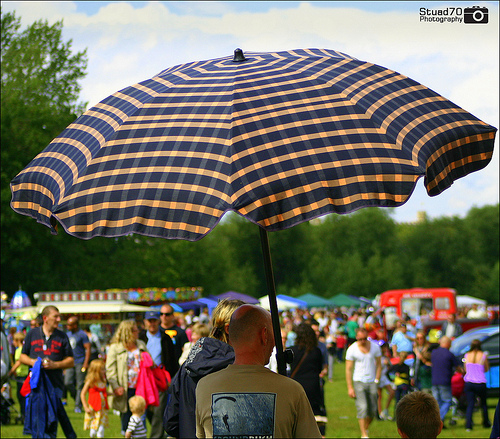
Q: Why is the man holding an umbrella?
A: Sun.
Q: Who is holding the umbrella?
A: Bald man.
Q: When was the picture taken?
A: Afternoon.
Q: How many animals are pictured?
A: 0.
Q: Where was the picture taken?
A: Fair.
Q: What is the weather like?
A: Sunny.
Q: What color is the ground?
A: Green.